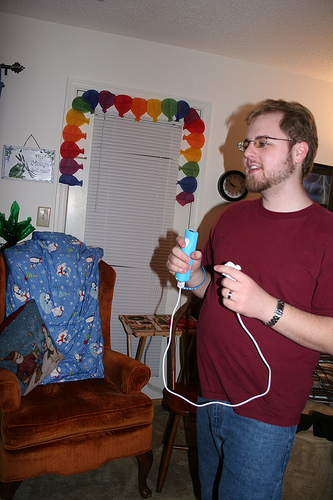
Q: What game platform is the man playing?
A: Wii.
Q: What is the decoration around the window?
A: Paper balloons.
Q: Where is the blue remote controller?
A: In his hands.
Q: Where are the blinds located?
A: On the window.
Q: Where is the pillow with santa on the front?
A: On the chair.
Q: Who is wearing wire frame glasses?
A: The man.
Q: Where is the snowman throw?
A: Hanging on the back of the chair.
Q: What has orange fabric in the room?
A: The chair.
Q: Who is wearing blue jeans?
A: The man.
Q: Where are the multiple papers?
A: On the door frame.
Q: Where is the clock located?
A: On the wall.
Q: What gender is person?
A: Male.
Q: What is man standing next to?
A: Chair.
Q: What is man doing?
A: Playing video game.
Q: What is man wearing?
A: Jeans.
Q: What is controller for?
A: Wii.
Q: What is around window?
A: Banner.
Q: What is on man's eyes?
A: Glasses.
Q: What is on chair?
A: Pillow.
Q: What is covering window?
A: Blinds.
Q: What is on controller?
A: Wire.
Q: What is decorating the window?
A: Balloon cutouts.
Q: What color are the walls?
A: White.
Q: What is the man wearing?
A: Glasses.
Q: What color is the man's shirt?
A: Red.